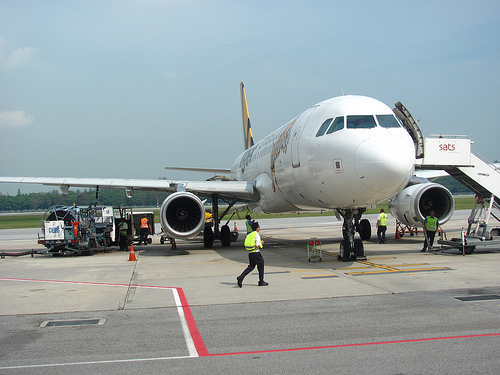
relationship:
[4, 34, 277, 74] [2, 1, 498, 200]
clouds in sky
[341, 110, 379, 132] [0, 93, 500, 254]
window of airplane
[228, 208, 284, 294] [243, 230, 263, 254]
man wearing vest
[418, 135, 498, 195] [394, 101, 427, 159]
stairs leading entrance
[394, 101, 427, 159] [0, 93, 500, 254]
entrance of airplane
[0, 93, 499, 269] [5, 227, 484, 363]
airplane on ground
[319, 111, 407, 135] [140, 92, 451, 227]
cockpit of airplane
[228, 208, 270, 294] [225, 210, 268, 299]
man on runway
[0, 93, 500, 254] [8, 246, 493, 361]
airplane on runeway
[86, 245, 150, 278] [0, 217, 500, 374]
orange cone on runway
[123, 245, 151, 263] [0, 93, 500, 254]
orange cone under airplane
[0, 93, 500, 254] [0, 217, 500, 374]
airplane on runway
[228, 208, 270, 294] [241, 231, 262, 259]
man with vest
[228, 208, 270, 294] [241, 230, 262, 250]
man with bag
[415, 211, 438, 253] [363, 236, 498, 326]
employee on tarmac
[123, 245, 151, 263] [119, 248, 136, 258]
orange cone with stripe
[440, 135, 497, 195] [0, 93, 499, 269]
stairs used to exit airplane